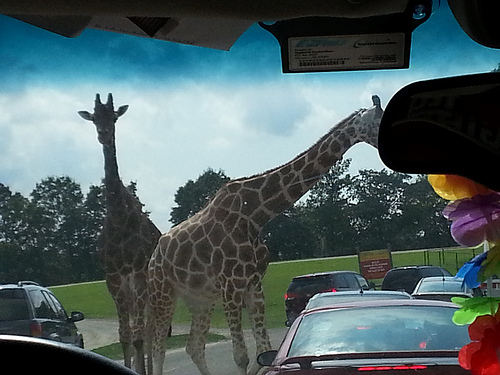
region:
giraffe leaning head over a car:
[139, 88, 404, 373]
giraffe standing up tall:
[77, 86, 164, 372]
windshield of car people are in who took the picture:
[0, 0, 499, 373]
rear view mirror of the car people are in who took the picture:
[372, 68, 498, 188]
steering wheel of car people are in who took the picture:
[1, 331, 141, 373]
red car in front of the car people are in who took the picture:
[248, 298, 497, 370]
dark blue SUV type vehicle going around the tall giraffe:
[0, 276, 88, 351]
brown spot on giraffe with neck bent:
[285, 171, 304, 201]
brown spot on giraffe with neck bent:
[191, 236, 214, 265]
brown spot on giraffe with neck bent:
[171, 242, 196, 271]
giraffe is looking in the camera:
[30, 76, 150, 184]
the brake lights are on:
[344, 355, 431, 373]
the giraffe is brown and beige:
[70, 172, 315, 297]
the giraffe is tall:
[75, 68, 177, 336]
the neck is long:
[230, 108, 368, 215]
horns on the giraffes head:
[74, 75, 122, 117]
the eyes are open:
[80, 105, 121, 130]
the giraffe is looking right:
[206, 61, 411, 291]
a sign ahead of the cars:
[330, 225, 402, 295]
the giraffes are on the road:
[78, 173, 278, 368]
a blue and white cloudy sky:
[0, 1, 499, 235]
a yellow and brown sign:
[357, 246, 393, 279]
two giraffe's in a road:
[77, 92, 384, 373]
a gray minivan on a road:
[0, 281, 83, 348]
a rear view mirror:
[377, 71, 498, 198]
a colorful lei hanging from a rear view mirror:
[424, 171, 498, 372]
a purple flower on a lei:
[442, 193, 499, 246]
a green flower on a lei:
[449, 296, 498, 325]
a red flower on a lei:
[458, 314, 497, 374]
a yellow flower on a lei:
[425, 172, 488, 197]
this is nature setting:
[6, 19, 455, 338]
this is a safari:
[63, 106, 395, 341]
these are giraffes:
[105, 123, 326, 359]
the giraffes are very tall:
[47, 91, 299, 357]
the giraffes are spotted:
[162, 190, 258, 315]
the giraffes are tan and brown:
[166, 209, 259, 314]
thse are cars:
[294, 261, 398, 363]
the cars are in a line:
[336, 251, 437, 365]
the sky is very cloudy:
[155, 76, 255, 151]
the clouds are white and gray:
[138, 82, 322, 154]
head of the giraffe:
[71, 77, 146, 147]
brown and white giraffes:
[146, 206, 251, 287]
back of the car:
[267, 290, 464, 360]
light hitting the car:
[275, 310, 357, 360]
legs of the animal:
[125, 270, 287, 365]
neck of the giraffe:
[71, 140, 143, 215]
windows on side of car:
[20, 275, 77, 326]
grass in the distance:
[267, 251, 322, 277]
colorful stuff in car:
[425, 185, 495, 355]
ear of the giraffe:
[112, 90, 142, 122]